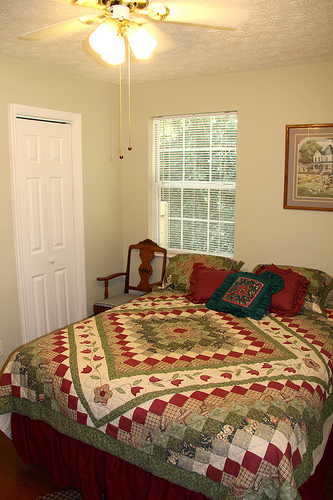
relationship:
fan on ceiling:
[18, 0, 247, 71] [0, 0, 332, 87]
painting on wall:
[273, 112, 331, 216] [123, 61, 328, 312]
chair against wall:
[92, 237, 168, 314] [120, 62, 332, 294]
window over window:
[149, 105, 239, 265] [147, 108, 240, 259]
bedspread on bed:
[0, 253, 331, 499] [4, 251, 328, 499]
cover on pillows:
[212, 272, 278, 315] [205, 265, 286, 327]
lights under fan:
[84, 18, 159, 64] [28, 4, 256, 39]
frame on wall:
[278, 104, 332, 222] [88, 71, 332, 476]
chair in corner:
[91, 237, 168, 318] [109, 81, 142, 304]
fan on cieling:
[18, 0, 248, 71] [1, 0, 332, 87]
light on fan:
[127, 28, 159, 52] [18, 0, 248, 71]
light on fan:
[127, 28, 159, 63] [18, 0, 248, 71]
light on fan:
[99, 36, 127, 65] [18, 0, 248, 71]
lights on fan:
[88, 18, 115, 60] [18, 0, 248, 71]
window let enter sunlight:
[147, 108, 240, 259] [150, 108, 238, 254]